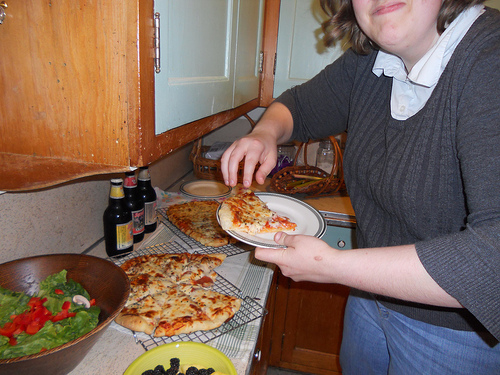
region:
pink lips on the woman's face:
[368, 0, 406, 16]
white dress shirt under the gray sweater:
[372, 0, 486, 122]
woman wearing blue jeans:
[336, 293, 498, 372]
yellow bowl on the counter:
[118, 340, 240, 374]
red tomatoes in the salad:
[3, 292, 73, 344]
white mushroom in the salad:
[69, 292, 94, 310]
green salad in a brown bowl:
[1, 249, 131, 374]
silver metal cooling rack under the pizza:
[103, 239, 268, 351]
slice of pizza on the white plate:
[218, 188, 298, 234]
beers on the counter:
[101, 164, 160, 258]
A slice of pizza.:
[220, 188, 297, 235]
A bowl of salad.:
[0, 250, 131, 374]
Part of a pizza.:
[153, 271, 193, 318]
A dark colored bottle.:
[103, 178, 133, 254]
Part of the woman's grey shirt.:
[312, 93, 346, 120]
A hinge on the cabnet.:
[150, 10, 162, 72]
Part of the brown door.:
[296, 308, 323, 351]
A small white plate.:
[179, 178, 230, 201]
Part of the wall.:
[43, 202, 72, 238]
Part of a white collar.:
[421, 57, 436, 87]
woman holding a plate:
[171, 3, 476, 363]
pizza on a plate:
[202, 160, 327, 271]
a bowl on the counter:
[0, 217, 130, 355]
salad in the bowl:
[6, 240, 124, 357]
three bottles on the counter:
[82, 160, 170, 246]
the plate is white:
[209, 176, 334, 257]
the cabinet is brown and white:
[67, 2, 274, 114]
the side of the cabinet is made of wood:
[37, 5, 174, 168]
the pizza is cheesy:
[189, 165, 305, 254]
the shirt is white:
[316, 26, 482, 156]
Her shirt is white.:
[370, 39, 490, 122]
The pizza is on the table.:
[120, 236, 243, 338]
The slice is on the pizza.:
[221, 151, 301, 251]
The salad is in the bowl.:
[7, 243, 128, 369]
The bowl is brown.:
[0, 237, 140, 371]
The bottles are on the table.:
[83, 156, 168, 256]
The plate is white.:
[207, 161, 332, 264]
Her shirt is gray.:
[272, 41, 498, 300]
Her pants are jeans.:
[333, 291, 498, 373]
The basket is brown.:
[258, 139, 350, 205]